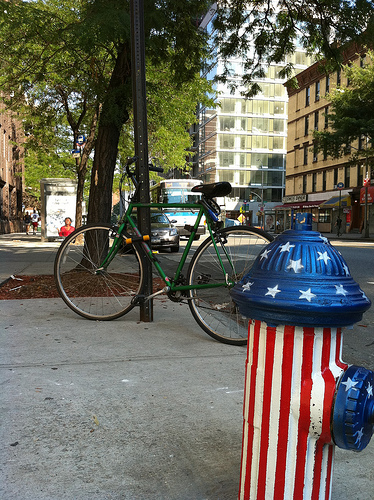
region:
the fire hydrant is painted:
[233, 211, 370, 498]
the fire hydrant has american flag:
[233, 211, 373, 496]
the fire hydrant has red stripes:
[245, 319, 353, 499]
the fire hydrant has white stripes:
[238, 318, 341, 498]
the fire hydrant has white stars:
[232, 210, 372, 452]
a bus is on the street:
[149, 180, 205, 236]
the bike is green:
[57, 160, 274, 347]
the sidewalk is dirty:
[0, 242, 372, 498]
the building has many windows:
[200, 2, 372, 201]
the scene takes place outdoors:
[0, 1, 373, 498]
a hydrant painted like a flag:
[230, 208, 372, 498]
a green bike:
[54, 157, 270, 341]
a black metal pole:
[128, 1, 155, 321]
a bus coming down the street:
[149, 177, 209, 237]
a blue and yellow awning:
[318, 193, 353, 209]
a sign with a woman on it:
[45, 193, 74, 237]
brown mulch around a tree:
[1, 270, 166, 298]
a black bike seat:
[191, 181, 232, 200]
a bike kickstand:
[176, 290, 218, 302]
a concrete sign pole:
[354, 171, 373, 236]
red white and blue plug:
[246, 221, 359, 474]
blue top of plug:
[211, 203, 368, 332]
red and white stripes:
[195, 330, 355, 473]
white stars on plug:
[248, 225, 338, 327]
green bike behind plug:
[69, 181, 252, 348]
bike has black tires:
[68, 238, 158, 311]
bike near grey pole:
[128, 36, 164, 272]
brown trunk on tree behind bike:
[56, 52, 148, 252]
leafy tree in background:
[12, 12, 205, 178]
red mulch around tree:
[18, 263, 144, 313]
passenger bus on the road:
[150, 180, 206, 237]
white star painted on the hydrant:
[265, 285, 283, 296]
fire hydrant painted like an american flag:
[234, 210, 372, 497]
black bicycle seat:
[189, 182, 231, 196]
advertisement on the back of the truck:
[55, 217, 75, 235]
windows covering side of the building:
[221, 13, 343, 201]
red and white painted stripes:
[245, 323, 327, 497]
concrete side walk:
[0, 231, 370, 496]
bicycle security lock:
[124, 233, 150, 245]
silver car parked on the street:
[126, 209, 179, 258]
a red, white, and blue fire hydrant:
[224, 205, 370, 497]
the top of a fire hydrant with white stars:
[228, 208, 372, 326]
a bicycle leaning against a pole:
[52, 155, 272, 342]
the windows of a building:
[299, 76, 323, 107]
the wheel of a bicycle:
[54, 223, 149, 321]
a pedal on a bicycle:
[130, 280, 169, 310]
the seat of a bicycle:
[186, 179, 239, 199]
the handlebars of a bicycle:
[125, 147, 164, 191]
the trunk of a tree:
[81, 161, 116, 276]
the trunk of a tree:
[70, 163, 86, 243]